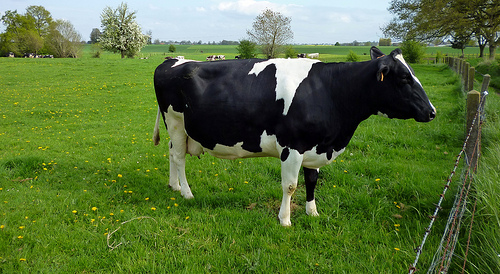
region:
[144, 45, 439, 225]
a cow standing in a field of grass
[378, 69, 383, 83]
a tag in the cow's ear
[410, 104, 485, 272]
rusted barbed wire on the fence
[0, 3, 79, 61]
a group of trees in the middle of the field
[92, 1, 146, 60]
a tree with white flowers on it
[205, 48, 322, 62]
more cows in the distance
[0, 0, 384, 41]
a partly cloudy sky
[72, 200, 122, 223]
yellow dandelions in the grass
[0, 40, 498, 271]
a large pasture with cows in it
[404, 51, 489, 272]
a long barbed wire fence on the edge of the pasture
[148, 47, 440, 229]
Cow standing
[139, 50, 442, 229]
Cow is standing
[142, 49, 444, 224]
Cow standing on the grass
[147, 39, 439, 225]
Cow is standing on the grass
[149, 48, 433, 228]
Black and white cow standing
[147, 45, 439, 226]
Black and white cow is standing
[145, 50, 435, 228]
Black and white cow standing on the grass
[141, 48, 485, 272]
Cow standing behind a fence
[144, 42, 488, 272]
Cow standing behind a barbed wire fence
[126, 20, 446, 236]
Black and white cow in a field.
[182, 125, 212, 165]
The udder on a cow.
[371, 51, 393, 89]
Tag in cow's ear.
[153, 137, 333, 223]
One of the cow's legs is mostly black.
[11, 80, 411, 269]
Yellow flowers growing in a field.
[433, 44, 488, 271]
A fence with wooden posts.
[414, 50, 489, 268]
A strand of barb wire.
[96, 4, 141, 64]
A tree with white blooms.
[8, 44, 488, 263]
A green, grassy field.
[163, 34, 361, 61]
Cows in the background.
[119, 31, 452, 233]
a cow inside the fence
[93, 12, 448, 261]
a black and white cow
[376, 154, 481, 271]
a barb wired fence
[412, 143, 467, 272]
a barb wired fence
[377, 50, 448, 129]
a white line on cow's face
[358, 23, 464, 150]
a white line on cow's face